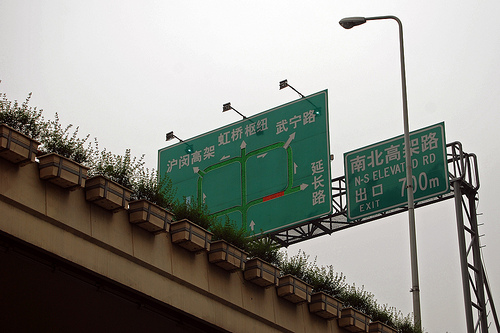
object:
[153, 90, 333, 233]
sign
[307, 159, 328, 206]
writing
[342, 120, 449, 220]
sign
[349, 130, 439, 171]
writing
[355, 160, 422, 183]
writing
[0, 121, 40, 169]
planter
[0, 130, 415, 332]
roadway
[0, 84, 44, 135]
plant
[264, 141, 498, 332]
sign support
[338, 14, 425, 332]
street lamp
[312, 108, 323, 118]
light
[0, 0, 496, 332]
sky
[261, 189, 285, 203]
mark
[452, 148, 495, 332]
ladder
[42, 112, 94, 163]
plant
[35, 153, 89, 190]
planter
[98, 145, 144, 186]
plant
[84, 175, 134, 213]
planter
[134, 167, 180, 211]
plant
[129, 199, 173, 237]
planter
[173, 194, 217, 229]
plant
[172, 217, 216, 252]
planter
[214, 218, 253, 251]
plant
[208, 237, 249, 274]
planter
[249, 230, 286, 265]
plant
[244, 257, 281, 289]
planter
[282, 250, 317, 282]
plant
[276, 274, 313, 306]
planter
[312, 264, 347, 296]
plant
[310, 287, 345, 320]
planter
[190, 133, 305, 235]
map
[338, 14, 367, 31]
light